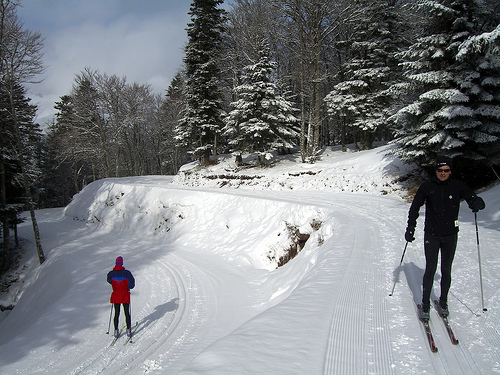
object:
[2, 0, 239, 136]
clouds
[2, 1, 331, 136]
sky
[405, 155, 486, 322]
man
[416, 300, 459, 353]
skis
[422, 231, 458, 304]
pants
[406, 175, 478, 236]
jacket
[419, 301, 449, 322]
boots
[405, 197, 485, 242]
gloves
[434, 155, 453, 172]
hat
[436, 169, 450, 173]
glasses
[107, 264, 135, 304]
coat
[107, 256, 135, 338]
person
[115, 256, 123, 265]
hat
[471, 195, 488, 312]
ski pole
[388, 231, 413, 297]
ski pole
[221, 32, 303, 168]
tree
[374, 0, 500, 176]
tree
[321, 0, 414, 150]
tree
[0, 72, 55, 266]
trees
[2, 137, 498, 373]
ground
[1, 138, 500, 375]
snow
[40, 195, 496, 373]
tracks